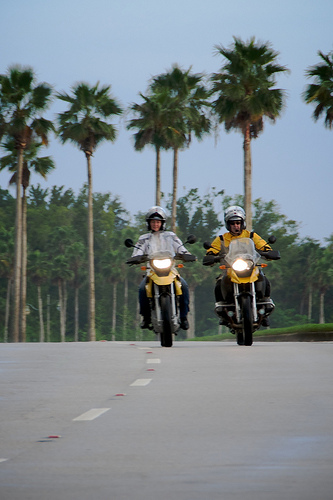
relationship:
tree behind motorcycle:
[206, 32, 290, 228] [198, 231, 282, 349]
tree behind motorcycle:
[158, 58, 214, 229] [198, 231, 282, 349]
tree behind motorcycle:
[121, 87, 162, 205] [198, 231, 282, 349]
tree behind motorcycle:
[48, 74, 126, 342] [198, 231, 282, 349]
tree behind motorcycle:
[1, 61, 59, 341] [198, 231, 282, 349]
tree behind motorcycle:
[206, 32, 290, 228] [121, 231, 198, 345]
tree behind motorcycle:
[158, 58, 214, 229] [121, 231, 198, 345]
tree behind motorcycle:
[121, 87, 162, 205] [121, 231, 198, 345]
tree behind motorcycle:
[48, 74, 126, 342] [121, 231, 198, 345]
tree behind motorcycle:
[1, 61, 59, 341] [121, 231, 198, 345]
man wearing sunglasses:
[203, 204, 270, 332] [227, 220, 243, 226]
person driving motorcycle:
[127, 202, 196, 329] [121, 231, 198, 345]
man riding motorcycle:
[200, 201, 278, 331] [198, 231, 282, 349]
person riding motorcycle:
[127, 202, 196, 329] [119, 232, 202, 348]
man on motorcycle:
[203, 204, 270, 332] [198, 231, 282, 349]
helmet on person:
[140, 210, 174, 231] [127, 202, 196, 329]